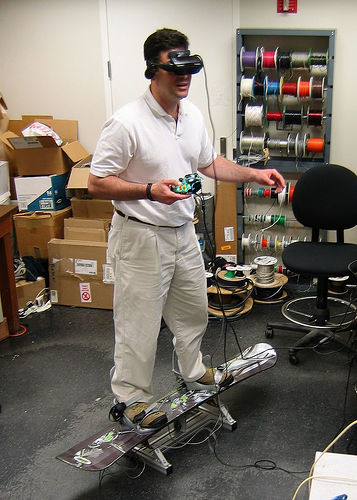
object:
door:
[104, 2, 237, 195]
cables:
[106, 52, 357, 500]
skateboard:
[56, 343, 277, 472]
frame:
[122, 389, 237, 478]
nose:
[179, 73, 189, 79]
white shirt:
[88, 81, 219, 227]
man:
[84, 26, 286, 433]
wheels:
[288, 353, 298, 365]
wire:
[166, 422, 225, 446]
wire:
[212, 426, 310, 475]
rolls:
[238, 42, 261, 73]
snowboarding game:
[53, 340, 277, 475]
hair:
[142, 27, 191, 76]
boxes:
[0, 118, 88, 175]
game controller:
[166, 171, 202, 195]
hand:
[255, 167, 286, 194]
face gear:
[144, 46, 203, 79]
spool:
[293, 52, 307, 65]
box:
[12, 172, 72, 214]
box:
[11, 202, 73, 261]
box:
[66, 152, 112, 200]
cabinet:
[236, 28, 336, 283]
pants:
[106, 210, 212, 405]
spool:
[246, 106, 261, 126]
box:
[47, 236, 119, 310]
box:
[61, 214, 114, 242]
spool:
[294, 76, 315, 100]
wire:
[298, 54, 307, 59]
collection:
[0, 92, 115, 316]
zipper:
[170, 228, 184, 266]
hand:
[150, 177, 192, 205]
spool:
[242, 49, 256, 67]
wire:
[244, 49, 251, 61]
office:
[3, 5, 345, 484]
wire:
[301, 81, 308, 95]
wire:
[248, 107, 259, 125]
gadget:
[107, 363, 168, 433]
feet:
[111, 391, 169, 437]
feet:
[177, 360, 236, 392]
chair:
[263, 161, 356, 365]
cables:
[235, 31, 327, 264]